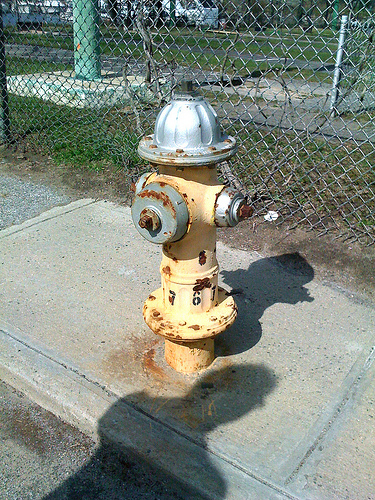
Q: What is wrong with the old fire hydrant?
A: Very rusty.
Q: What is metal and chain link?
A: The fence.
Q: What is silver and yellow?
A: Fire hydrant.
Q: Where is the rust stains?
A: On the sidewalk.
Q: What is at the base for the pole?
A: Concrete.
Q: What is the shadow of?
A: Fire hydrant.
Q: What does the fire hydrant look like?
A: Rusty yellow.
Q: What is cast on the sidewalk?
A: The shadow of a person.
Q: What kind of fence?
A: Chain link.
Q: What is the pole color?
A: Green.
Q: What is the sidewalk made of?
A: Gravel.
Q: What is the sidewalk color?
A: Gray.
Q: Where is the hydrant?
A: Sidewalk.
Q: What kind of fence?
A: Metal.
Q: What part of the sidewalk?
A: Curb.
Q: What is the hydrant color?
A: Yellow.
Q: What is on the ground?
A: Shadow.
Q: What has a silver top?
A: Fire hydrant.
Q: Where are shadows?
A: On the ground.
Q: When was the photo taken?
A: During daytime.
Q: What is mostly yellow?
A: The fire hydrant.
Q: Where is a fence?
A: Behind fire hydrant.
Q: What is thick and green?
A: A pole.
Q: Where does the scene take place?
A: On a sidewalk.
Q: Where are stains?
A: On sidewalk around fire hydrant.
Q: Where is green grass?
A: Behind the fence.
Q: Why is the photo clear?
A: Its daytime.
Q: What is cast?
A: Shadow.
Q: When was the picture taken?
A: During the day.